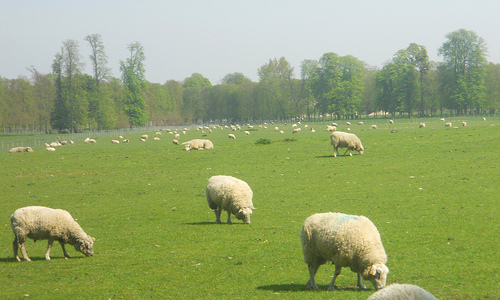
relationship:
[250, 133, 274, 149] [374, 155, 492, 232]
bush in field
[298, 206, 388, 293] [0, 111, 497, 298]
sheep in field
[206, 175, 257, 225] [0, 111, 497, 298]
sheep in field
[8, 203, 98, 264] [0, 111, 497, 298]
sheep in field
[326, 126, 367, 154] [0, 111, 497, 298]
sheep in field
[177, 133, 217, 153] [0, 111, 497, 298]
sheep in field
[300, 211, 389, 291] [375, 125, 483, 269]
sheep eating grass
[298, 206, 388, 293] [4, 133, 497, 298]
sheep in field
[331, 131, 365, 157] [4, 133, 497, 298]
sheep in field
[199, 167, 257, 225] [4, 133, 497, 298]
sheep in field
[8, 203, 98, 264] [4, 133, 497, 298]
sheep in field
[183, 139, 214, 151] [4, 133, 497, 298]
sheep in field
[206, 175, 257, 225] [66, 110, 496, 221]
sheep in field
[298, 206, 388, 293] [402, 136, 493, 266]
sheep in field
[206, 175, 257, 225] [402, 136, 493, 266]
sheep in field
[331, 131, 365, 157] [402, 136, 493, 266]
sheep in field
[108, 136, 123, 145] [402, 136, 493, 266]
sheep in field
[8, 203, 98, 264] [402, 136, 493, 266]
sheep in field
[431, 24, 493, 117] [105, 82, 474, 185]
trees in field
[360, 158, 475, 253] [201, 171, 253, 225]
grass under sheep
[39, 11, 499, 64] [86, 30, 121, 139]
sky above tree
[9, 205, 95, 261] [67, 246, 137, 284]
sheep eating grass